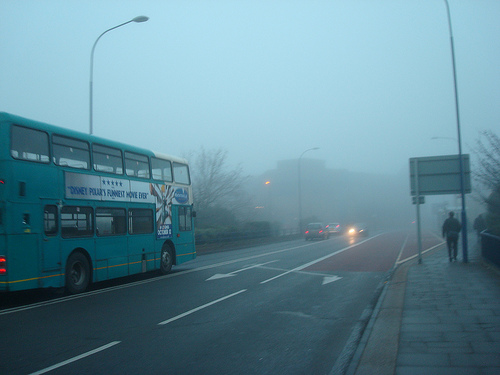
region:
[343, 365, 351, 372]
White goggles on top of man's head.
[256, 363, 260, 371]
White goggles on top of man's head.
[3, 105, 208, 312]
blue double decker bus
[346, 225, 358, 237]
one headlight shining brightly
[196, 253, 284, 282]
white arrow painted on the ground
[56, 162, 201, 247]
advertisement on the side of the bus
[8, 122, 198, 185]
row of windows on the top of the bus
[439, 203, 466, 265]
person walking on the sidewalk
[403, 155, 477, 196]
back of a sign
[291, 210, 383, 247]
three cars on the road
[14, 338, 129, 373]
white line painted on the ground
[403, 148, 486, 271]
person walking under the sign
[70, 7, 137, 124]
light pole over bus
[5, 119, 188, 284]
teal double decker bus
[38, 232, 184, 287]
black tires on bus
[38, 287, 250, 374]
white lines on road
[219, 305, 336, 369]
road is dark grey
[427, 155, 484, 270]
man is under sign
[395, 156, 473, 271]
sign on grey poles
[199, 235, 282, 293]
white arrow on road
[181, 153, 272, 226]
bare tree behind bus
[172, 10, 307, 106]
grey and rainy sky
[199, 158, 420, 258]
fog along the street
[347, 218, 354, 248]
bright car light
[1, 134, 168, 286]
tourist buss along the street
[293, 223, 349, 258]
car with red lights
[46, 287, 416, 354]
white markings on the street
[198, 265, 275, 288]
white arrow on the street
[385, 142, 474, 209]
large sign facing opposite direction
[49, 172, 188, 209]
advertisement on the bus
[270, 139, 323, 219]
street light covered in fog